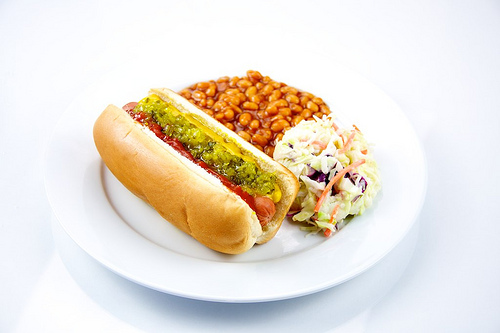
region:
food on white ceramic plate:
[65, 43, 444, 305]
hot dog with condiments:
[91, 86, 304, 265]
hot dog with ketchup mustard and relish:
[110, 85, 301, 265]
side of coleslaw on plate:
[281, 118, 374, 223]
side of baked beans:
[194, 77, 309, 122]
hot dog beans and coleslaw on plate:
[95, 66, 380, 242]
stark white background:
[386, 17, 496, 318]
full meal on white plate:
[83, 53, 421, 274]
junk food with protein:
[93, 58, 402, 260]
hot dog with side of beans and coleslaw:
[91, 72, 387, 254]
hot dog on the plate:
[91, 89, 287, 255]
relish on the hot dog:
[140, 97, 274, 211]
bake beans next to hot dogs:
[203, 56, 323, 150]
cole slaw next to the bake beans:
[265, 120, 370, 240]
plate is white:
[85, 188, 355, 309]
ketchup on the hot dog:
[127, 107, 261, 210]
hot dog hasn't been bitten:
[123, 96, 298, 243]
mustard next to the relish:
[144, 96, 284, 201]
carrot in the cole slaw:
[299, 147, 357, 214]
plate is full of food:
[111, 69, 381, 283]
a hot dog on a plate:
[56, 95, 289, 261]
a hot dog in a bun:
[81, 96, 287, 243]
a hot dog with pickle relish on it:
[126, 75, 289, 242]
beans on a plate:
[193, 56, 353, 163]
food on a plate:
[74, 51, 451, 308]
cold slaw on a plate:
[281, 81, 411, 226]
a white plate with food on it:
[101, 37, 439, 295]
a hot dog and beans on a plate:
[93, 81, 318, 254]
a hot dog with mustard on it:
[91, 67, 331, 246]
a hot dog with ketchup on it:
[108, 84, 292, 261]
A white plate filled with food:
[46, 55, 426, 301]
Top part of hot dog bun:
[91, 105, 261, 255]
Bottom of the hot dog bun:
[160, 85, 300, 245]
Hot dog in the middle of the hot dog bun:
[131, 110, 276, 228]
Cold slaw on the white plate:
[273, 117, 380, 234]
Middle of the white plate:
[100, 153, 358, 263]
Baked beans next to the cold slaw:
[176, 70, 329, 157]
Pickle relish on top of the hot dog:
[140, 92, 276, 193]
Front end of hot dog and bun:
[211, 161, 301, 254]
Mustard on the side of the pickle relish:
[154, 85, 258, 170]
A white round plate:
[71, 65, 428, 301]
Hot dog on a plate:
[86, 85, 301, 260]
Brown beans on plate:
[179, 66, 334, 158]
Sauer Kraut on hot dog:
[131, 92, 281, 199]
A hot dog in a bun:
[87, 86, 304, 258]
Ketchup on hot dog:
[124, 107, 260, 214]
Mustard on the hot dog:
[152, 89, 282, 204]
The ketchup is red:
[124, 105, 256, 210]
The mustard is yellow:
[158, 95, 284, 205]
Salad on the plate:
[273, 110, 378, 240]